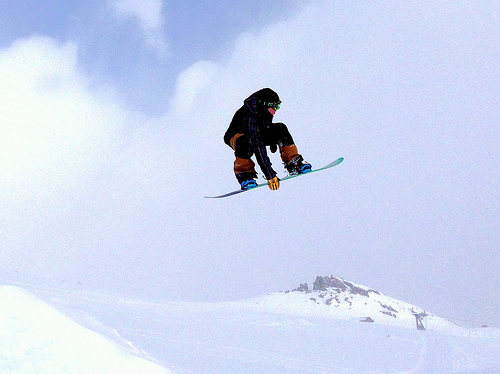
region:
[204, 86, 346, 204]
man on blue snowboard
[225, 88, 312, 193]
person wearing black ski suit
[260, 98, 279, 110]
person wearing ski goggles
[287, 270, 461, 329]
mountain with gray tip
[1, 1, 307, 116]
blue sky with clouds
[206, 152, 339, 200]
person holding snowboard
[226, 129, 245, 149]
red strip on arm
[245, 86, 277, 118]
person wearing black hat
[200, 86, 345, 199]
snowboarder doing trick in air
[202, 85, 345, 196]
snowboarder in the air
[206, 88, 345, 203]
a person on a snowboard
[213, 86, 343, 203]
a person jumping on a snowboard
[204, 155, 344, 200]
a snowboard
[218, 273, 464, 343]
the top of a snowy mountain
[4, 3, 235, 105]
a cloudy blue sky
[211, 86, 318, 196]
a person wearing a black jacket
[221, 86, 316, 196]
a man wearing a yellow glove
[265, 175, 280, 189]
the yellow glove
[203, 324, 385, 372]
tracks in the snow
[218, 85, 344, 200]
a man is wearing goggles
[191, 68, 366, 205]
skier in the air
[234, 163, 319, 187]
blue boots on skier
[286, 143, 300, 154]
brown high socks on left leg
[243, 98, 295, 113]
goggles on his face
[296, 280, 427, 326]
snow on the mountain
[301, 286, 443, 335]
mountain in the distance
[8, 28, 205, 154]
clouds in the sky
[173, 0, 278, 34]
blue sky in between clouds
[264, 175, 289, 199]
right hand on ski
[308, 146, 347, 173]
top of ski is blue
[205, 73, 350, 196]
a person snow boarding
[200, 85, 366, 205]
a snow boarder in the air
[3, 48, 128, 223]
the clouds are white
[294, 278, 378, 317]
rocks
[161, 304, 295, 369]
the snow is white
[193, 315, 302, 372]
the snow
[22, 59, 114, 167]
the sky has clouds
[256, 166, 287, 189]
person is holding snow board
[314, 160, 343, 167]
the snow board is blue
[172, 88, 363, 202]
person is in the air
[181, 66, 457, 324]
a snowboarder making a jump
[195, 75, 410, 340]
a snowboarder doing a jump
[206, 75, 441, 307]
a snowboarder catching air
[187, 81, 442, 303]
a snowboarder doing a stunt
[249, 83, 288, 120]
the head of a snowboarder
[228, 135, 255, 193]
the leg of a snowboarder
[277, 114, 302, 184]
the leg of a snowboarder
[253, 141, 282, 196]
the arm of a snowboarder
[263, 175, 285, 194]
the hand of a snowboarder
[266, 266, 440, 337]
a snowy mountaintop